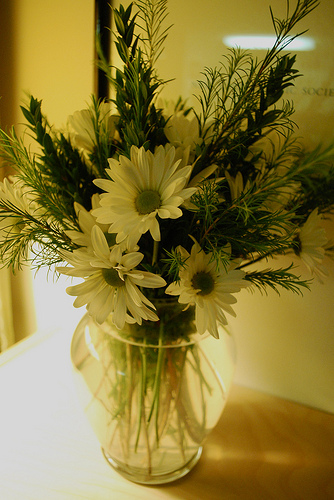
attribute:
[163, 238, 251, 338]
flower — white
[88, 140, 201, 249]
flower — grey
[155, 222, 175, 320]
stem — long, green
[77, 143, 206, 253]
flower — white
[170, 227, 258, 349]
flower — white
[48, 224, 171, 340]
flower — white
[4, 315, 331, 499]
table — wooden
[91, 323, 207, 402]
vase — clear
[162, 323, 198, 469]
stems — brown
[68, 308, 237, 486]
vase — glass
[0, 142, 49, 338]
curtain — white, in back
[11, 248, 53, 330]
drapes — in background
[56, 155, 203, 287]
middle — green, brown